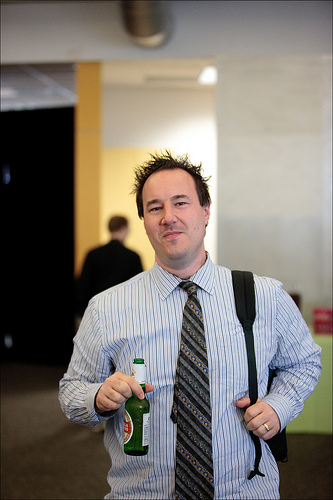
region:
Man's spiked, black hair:
[127, 145, 210, 193]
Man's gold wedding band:
[258, 421, 273, 434]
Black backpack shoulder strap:
[225, 266, 269, 484]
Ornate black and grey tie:
[168, 301, 216, 499]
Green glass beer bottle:
[116, 355, 158, 458]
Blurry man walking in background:
[69, 210, 142, 330]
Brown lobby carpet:
[0, 431, 102, 499]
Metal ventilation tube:
[100, 0, 196, 49]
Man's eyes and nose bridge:
[144, 186, 193, 219]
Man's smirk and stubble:
[154, 221, 200, 263]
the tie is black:
[189, 447, 194, 455]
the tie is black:
[191, 452, 198, 467]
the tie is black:
[191, 461, 198, 477]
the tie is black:
[203, 471, 211, 483]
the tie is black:
[187, 467, 196, 488]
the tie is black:
[184, 449, 193, 470]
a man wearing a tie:
[176, 390, 232, 497]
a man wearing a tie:
[163, 450, 199, 495]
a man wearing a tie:
[163, 384, 188, 466]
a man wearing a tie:
[159, 434, 188, 478]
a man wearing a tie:
[186, 424, 215, 483]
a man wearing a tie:
[155, 425, 180, 486]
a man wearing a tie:
[186, 459, 200, 496]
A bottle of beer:
[103, 290, 146, 446]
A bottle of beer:
[94, 371, 142, 488]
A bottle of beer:
[109, 363, 162, 489]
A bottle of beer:
[124, 383, 183, 476]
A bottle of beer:
[72, 313, 139, 431]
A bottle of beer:
[129, 416, 150, 453]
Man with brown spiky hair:
[123, 151, 243, 328]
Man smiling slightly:
[133, 143, 251, 331]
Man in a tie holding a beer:
[98, 155, 224, 436]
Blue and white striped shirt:
[106, 255, 287, 489]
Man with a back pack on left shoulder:
[120, 161, 282, 453]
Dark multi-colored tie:
[174, 271, 213, 406]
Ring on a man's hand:
[230, 393, 304, 450]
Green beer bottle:
[116, 356, 165, 461]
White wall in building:
[218, 28, 331, 233]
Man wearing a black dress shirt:
[72, 137, 143, 282]